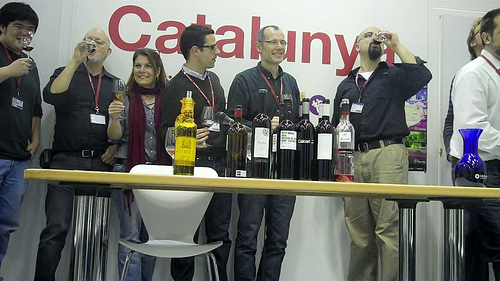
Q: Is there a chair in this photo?
A: Yes, there is a chair.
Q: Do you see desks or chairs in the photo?
A: Yes, there is a chair.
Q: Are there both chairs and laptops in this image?
A: No, there is a chair but no laptops.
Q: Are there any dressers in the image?
A: No, there are no dressers.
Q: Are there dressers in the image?
A: No, there are no dressers.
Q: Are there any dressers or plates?
A: No, there are no dressers or plates.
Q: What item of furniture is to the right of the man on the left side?
A: The piece of furniture is a chair.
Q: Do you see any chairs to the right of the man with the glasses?
A: Yes, there is a chair to the right of the man.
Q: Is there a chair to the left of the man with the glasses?
A: No, the chair is to the right of the man.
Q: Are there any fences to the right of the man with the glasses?
A: No, there is a chair to the right of the man.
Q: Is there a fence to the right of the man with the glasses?
A: No, there is a chair to the right of the man.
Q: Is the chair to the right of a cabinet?
A: No, the chair is to the right of a man.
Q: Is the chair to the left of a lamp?
A: No, the chair is to the left of a man.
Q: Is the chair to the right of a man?
A: No, the chair is to the left of a man.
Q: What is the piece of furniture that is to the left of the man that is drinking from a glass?
A: The piece of furniture is a chair.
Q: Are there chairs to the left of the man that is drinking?
A: Yes, there is a chair to the left of the man.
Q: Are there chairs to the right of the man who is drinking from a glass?
A: No, the chair is to the left of the man.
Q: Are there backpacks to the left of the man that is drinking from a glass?
A: No, there is a chair to the left of the man.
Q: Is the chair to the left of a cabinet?
A: No, the chair is to the left of the man.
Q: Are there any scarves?
A: Yes, there is a scarf.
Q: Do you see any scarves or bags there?
A: Yes, there is a scarf.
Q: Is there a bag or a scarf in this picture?
A: Yes, there is a scarf.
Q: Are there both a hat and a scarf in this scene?
A: No, there is a scarf but no hats.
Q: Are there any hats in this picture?
A: No, there are no hats.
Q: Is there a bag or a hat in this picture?
A: No, there are no hats or bags.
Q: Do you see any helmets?
A: No, there are no helmets.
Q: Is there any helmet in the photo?
A: No, there are no helmets.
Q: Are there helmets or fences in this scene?
A: No, there are no helmets or fences.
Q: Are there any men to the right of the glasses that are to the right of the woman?
A: Yes, there is a man to the right of the glasses.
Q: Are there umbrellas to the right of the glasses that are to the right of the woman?
A: No, there is a man to the right of the glasses.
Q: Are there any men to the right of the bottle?
A: Yes, there is a man to the right of the bottle.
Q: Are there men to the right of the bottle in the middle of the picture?
A: Yes, there is a man to the right of the bottle.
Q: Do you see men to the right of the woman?
A: Yes, there is a man to the right of the woman.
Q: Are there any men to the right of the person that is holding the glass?
A: Yes, there is a man to the right of the woman.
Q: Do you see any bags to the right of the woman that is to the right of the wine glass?
A: No, there is a man to the right of the woman.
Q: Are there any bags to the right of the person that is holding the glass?
A: No, there is a man to the right of the woman.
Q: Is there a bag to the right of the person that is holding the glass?
A: No, there is a man to the right of the woman.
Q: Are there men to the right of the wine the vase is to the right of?
A: No, the man is to the left of the wine.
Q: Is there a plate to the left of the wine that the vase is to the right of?
A: No, there is a man to the left of the wine.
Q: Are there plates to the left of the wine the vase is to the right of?
A: No, there is a man to the left of the wine.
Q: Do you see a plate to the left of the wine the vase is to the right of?
A: No, there is a man to the left of the wine.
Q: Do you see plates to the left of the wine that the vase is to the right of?
A: No, there is a man to the left of the wine.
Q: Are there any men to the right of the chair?
A: Yes, there is a man to the right of the chair.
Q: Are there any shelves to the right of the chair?
A: No, there is a man to the right of the chair.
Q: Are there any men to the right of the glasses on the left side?
A: Yes, there is a man to the right of the glasses.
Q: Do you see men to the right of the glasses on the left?
A: Yes, there is a man to the right of the glasses.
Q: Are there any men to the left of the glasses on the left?
A: No, the man is to the right of the glasses.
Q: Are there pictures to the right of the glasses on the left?
A: No, there is a man to the right of the glasses.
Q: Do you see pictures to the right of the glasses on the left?
A: No, there is a man to the right of the glasses.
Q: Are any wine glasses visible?
A: Yes, there is a wine glass.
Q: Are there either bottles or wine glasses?
A: Yes, there is a wine glass.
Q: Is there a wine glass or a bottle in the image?
A: Yes, there is a wine glass.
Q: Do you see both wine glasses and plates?
A: No, there is a wine glass but no plates.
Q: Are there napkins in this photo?
A: No, there are no napkins.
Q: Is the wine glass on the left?
A: Yes, the wine glass is on the left of the image.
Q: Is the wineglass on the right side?
A: No, the wineglass is on the left of the image.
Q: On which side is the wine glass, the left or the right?
A: The wine glass is on the left of the image.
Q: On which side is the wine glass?
A: The wine glass is on the left of the image.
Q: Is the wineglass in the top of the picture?
A: Yes, the wineglass is in the top of the image.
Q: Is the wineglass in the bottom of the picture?
A: No, the wineglass is in the top of the image.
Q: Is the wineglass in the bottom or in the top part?
A: The wineglass is in the top of the image.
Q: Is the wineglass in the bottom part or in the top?
A: The wineglass is in the top of the image.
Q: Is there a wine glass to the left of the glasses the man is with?
A: Yes, there is a wine glass to the left of the glasses.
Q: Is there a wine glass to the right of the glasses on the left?
A: No, the wine glass is to the left of the glasses.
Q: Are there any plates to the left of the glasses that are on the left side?
A: No, there is a wine glass to the left of the glasses.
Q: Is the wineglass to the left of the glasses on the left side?
A: Yes, the wineglass is to the left of the glasses.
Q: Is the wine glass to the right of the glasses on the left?
A: No, the wine glass is to the left of the glasses.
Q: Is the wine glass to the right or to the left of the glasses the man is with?
A: The wine glass is to the left of the glasses.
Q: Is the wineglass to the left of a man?
A: Yes, the wineglass is to the left of a man.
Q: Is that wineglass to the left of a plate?
A: No, the wineglass is to the left of a man.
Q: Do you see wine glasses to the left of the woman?
A: Yes, there is a wine glass to the left of the woman.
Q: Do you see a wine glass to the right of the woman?
A: No, the wine glass is to the left of the woman.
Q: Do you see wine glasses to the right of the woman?
A: No, the wine glass is to the left of the woman.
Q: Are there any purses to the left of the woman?
A: No, there is a wine glass to the left of the woman.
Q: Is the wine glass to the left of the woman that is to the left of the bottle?
A: Yes, the wine glass is to the left of the woman.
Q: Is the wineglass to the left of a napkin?
A: No, the wineglass is to the left of the woman.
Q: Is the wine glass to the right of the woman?
A: No, the wine glass is to the left of the woman.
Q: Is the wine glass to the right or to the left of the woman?
A: The wine glass is to the left of the woman.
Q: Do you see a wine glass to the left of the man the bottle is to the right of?
A: Yes, there is a wine glass to the left of the man.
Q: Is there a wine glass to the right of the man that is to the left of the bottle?
A: No, the wine glass is to the left of the man.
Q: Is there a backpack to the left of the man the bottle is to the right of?
A: No, there is a wine glass to the left of the man.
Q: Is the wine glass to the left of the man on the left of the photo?
A: Yes, the wine glass is to the left of the man.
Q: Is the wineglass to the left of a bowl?
A: No, the wineglass is to the left of the man.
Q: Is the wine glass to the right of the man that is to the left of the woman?
A: No, the wine glass is to the left of the man.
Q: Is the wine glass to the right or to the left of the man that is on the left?
A: The wine glass is to the left of the man.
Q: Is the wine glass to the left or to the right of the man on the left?
A: The wine glass is to the left of the man.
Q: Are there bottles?
A: Yes, there is a bottle.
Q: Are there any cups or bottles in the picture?
A: Yes, there is a bottle.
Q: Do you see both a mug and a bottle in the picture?
A: No, there is a bottle but no mugs.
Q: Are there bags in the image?
A: No, there are no bags.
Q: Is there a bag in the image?
A: No, there are no bags.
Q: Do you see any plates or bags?
A: No, there are no bags or plates.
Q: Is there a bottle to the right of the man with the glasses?
A: Yes, there is a bottle to the right of the man.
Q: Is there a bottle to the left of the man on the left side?
A: No, the bottle is to the right of the man.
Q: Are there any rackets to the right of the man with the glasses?
A: No, there is a bottle to the right of the man.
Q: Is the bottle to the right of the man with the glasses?
A: Yes, the bottle is to the right of the man.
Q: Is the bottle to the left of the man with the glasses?
A: No, the bottle is to the right of the man.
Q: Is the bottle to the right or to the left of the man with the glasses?
A: The bottle is to the right of the man.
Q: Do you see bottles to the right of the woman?
A: Yes, there is a bottle to the right of the woman.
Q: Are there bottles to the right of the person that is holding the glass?
A: Yes, there is a bottle to the right of the woman.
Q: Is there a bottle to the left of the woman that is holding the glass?
A: No, the bottle is to the right of the woman.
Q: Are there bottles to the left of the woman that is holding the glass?
A: No, the bottle is to the right of the woman.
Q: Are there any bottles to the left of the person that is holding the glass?
A: No, the bottle is to the right of the woman.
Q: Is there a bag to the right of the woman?
A: No, there is a bottle to the right of the woman.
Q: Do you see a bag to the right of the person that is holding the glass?
A: No, there is a bottle to the right of the woman.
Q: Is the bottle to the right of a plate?
A: No, the bottle is to the right of a woman.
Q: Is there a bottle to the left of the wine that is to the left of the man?
A: Yes, there is a bottle to the left of the wine.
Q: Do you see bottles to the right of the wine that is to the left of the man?
A: No, the bottle is to the left of the wine.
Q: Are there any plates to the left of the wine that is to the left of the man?
A: No, there is a bottle to the left of the wine.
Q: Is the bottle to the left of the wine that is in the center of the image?
A: Yes, the bottle is to the left of the wine.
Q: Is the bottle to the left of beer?
A: No, the bottle is to the left of the wine.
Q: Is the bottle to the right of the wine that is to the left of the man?
A: No, the bottle is to the left of the wine.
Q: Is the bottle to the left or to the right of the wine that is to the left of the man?
A: The bottle is to the left of the wine.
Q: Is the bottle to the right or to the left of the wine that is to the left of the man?
A: The bottle is to the left of the wine.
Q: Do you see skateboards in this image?
A: No, there are no skateboards.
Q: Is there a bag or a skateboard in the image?
A: No, there are no skateboards or bags.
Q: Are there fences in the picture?
A: No, there are no fences.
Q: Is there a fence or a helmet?
A: No, there are no fences or helmets.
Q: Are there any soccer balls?
A: No, there are no soccer balls.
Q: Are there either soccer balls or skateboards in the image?
A: No, there are no soccer balls or skateboards.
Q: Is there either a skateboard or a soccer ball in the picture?
A: No, there are no soccer balls or skateboards.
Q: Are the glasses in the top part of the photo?
A: Yes, the glasses are in the top of the image.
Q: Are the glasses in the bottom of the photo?
A: No, the glasses are in the top of the image.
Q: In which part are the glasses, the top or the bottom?
A: The glasses are in the top of the image.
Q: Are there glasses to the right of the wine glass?
A: Yes, there are glasses to the right of the wine glass.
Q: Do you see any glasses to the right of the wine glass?
A: Yes, there are glasses to the right of the wine glass.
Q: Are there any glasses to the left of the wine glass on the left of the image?
A: No, the glasses are to the right of the wineglass.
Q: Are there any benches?
A: No, there are no benches.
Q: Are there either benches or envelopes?
A: No, there are no benches or envelopes.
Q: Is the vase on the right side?
A: Yes, the vase is on the right of the image.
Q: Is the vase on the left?
A: No, the vase is on the right of the image.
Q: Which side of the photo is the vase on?
A: The vase is on the right of the image.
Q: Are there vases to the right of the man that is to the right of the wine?
A: Yes, there is a vase to the right of the man.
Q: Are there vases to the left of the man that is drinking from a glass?
A: No, the vase is to the right of the man.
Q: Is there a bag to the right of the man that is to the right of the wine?
A: No, there is a vase to the right of the man.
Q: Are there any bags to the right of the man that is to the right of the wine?
A: No, there is a vase to the right of the man.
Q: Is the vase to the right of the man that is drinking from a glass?
A: Yes, the vase is to the right of the man.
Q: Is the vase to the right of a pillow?
A: No, the vase is to the right of the man.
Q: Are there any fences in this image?
A: No, there are no fences.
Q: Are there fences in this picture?
A: No, there are no fences.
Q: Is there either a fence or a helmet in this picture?
A: No, there are no fences or helmets.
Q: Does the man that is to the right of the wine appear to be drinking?
A: Yes, the man is drinking.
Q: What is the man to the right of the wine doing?
A: The man is drinking.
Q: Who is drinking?
A: The man is drinking.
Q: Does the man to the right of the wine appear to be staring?
A: No, the man is drinking.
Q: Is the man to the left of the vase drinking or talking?
A: The man is drinking.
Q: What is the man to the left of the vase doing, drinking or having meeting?
A: The man is drinking.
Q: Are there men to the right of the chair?
A: Yes, there is a man to the right of the chair.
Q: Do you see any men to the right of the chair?
A: Yes, there is a man to the right of the chair.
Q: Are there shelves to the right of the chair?
A: No, there is a man to the right of the chair.